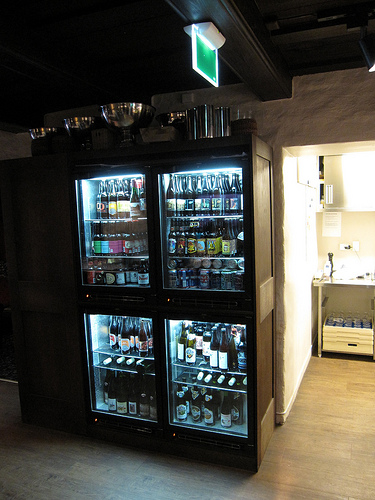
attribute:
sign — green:
[184, 23, 226, 89]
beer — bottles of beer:
[93, 183, 154, 217]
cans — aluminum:
[165, 259, 242, 289]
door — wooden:
[251, 133, 290, 427]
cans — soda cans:
[170, 258, 244, 292]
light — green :
[183, 21, 228, 83]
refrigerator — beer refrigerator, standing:
[56, 156, 255, 459]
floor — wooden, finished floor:
[0, 355, 373, 498]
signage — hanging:
[182, 19, 227, 87]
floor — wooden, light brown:
[9, 433, 77, 486]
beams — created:
[166, 3, 298, 103]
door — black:
[69, 170, 154, 288]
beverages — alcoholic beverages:
[157, 166, 244, 224]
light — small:
[85, 292, 90, 297]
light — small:
[163, 296, 175, 305]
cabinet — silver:
[304, 151, 336, 201]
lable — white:
[175, 403, 186, 419]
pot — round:
[100, 99, 155, 147]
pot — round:
[60, 116, 103, 151]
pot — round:
[27, 125, 56, 146]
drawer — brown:
[321, 315, 372, 357]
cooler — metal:
[74, 131, 277, 470]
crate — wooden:
[321, 314, 373, 356]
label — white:
[150, 197, 216, 210]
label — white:
[212, 345, 229, 374]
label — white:
[219, 349, 229, 369]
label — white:
[202, 406, 214, 425]